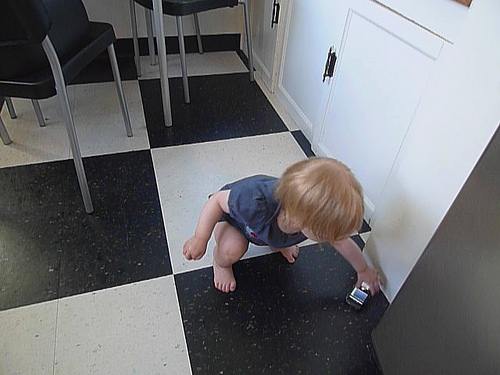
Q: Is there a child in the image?
A: Yes, there is a child.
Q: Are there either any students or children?
A: Yes, there is a child.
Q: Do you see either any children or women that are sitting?
A: Yes, the child is sitting.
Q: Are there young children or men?
A: Yes, there is a young child.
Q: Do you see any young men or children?
A: Yes, there is a young child.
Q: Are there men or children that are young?
A: Yes, the child is young.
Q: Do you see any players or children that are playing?
A: Yes, the child is playing.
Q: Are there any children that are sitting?
A: Yes, there is a child that is sitting.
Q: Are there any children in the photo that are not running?
A: Yes, there is a child that is sitting.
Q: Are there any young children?
A: Yes, there is a young child.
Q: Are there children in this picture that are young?
A: Yes, there is a child that is young.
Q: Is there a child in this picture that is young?
A: Yes, there is a child that is young.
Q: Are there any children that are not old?
A: Yes, there is an young child.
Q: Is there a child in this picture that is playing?
A: Yes, there is a child that is playing.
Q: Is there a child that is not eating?
A: Yes, there is a child that is playing.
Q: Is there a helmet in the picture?
A: No, there are no helmets.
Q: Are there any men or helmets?
A: No, there are no helmets or men.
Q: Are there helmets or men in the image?
A: No, there are no helmets or men.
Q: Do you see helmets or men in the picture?
A: No, there are no helmets or men.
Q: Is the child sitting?
A: Yes, the child is sitting.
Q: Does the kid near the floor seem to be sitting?
A: Yes, the kid is sitting.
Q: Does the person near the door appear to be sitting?
A: Yes, the kid is sitting.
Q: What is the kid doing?
A: The kid is sitting.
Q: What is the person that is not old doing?
A: The kid is sitting.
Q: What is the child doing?
A: The kid is sitting.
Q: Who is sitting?
A: The child is sitting.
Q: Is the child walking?
A: No, the child is sitting.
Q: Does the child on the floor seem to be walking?
A: No, the child is sitting.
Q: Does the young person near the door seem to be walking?
A: No, the child is sitting.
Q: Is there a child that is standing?
A: No, there is a child but he is sitting.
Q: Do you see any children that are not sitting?
A: No, there is a child but he is sitting.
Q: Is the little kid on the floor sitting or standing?
A: The kid is sitting.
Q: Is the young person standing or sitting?
A: The kid is sitting.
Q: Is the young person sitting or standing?
A: The kid is sitting.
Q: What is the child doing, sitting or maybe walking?
A: The child is sitting.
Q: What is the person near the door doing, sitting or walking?
A: The child is sitting.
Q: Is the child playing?
A: Yes, the child is playing.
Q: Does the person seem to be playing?
A: Yes, the kid is playing.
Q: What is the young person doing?
A: The child is playing.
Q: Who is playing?
A: The child is playing.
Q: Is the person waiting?
A: No, the kid is playing.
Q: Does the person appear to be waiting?
A: No, the kid is playing.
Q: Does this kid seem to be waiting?
A: No, the kid is playing.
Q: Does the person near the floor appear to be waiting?
A: No, the kid is playing.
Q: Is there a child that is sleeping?
A: No, there is a child but he is playing.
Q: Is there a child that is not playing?
A: No, there is a child but he is playing.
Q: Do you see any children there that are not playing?
A: No, there is a child but he is playing.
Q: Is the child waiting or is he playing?
A: The child is playing.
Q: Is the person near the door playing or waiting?
A: The child is playing.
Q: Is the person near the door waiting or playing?
A: The child is playing.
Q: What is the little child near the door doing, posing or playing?
A: The child is playing.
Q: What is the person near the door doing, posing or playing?
A: The child is playing.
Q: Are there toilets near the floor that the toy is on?
A: No, there is a child near the floor.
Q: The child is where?
A: The child is on the floor.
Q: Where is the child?
A: The child is on the floor.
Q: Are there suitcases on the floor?
A: No, there is a child on the floor.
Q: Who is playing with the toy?
A: The kid is playing with the toy.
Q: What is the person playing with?
A: The kid is playing with a toy.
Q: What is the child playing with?
A: The kid is playing with a toy.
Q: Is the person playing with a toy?
A: Yes, the kid is playing with a toy.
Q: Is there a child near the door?
A: Yes, there is a child near the door.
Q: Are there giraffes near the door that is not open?
A: No, there is a child near the door.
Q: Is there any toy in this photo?
A: Yes, there is a toy.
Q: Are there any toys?
A: Yes, there is a toy.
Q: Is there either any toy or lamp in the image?
A: Yes, there is a toy.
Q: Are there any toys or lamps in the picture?
A: Yes, there is a toy.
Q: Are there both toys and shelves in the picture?
A: No, there is a toy but no shelves.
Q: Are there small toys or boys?
A: Yes, there is a small toy.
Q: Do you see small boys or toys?
A: Yes, there is a small toy.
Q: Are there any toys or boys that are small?
A: Yes, the toy is small.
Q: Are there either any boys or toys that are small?
A: Yes, the toy is small.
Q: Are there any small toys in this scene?
A: Yes, there is a small toy.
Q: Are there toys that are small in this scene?
A: Yes, there is a small toy.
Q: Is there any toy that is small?
A: Yes, there is a toy that is small.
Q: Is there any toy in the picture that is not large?
A: Yes, there is a small toy.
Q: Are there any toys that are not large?
A: Yes, there is a small toy.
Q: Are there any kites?
A: No, there are no kites.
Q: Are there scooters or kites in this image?
A: No, there are no kites or scooters.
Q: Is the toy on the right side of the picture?
A: Yes, the toy is on the right of the image.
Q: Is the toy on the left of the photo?
A: No, the toy is on the right of the image.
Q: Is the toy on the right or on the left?
A: The toy is on the right of the image.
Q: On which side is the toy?
A: The toy is on the right of the image.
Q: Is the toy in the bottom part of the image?
A: Yes, the toy is in the bottom of the image.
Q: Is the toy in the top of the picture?
A: No, the toy is in the bottom of the image.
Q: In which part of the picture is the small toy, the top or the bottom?
A: The toy is in the bottom of the image.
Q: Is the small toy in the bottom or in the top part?
A: The toy is in the bottom of the image.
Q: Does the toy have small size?
A: Yes, the toy is small.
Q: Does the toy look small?
A: Yes, the toy is small.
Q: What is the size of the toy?
A: The toy is small.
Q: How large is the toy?
A: The toy is small.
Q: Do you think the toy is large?
A: No, the toy is small.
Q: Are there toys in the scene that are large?
A: No, there is a toy but it is small.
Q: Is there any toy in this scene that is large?
A: No, there is a toy but it is small.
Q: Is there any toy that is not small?
A: No, there is a toy but it is small.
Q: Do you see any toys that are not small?
A: No, there is a toy but it is small.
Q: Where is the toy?
A: The toy is on the floor.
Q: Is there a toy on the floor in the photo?
A: Yes, there is a toy on the floor.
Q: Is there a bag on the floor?
A: No, there is a toy on the floor.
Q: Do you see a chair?
A: Yes, there is a chair.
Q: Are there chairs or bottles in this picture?
A: Yes, there is a chair.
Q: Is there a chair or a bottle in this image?
A: Yes, there is a chair.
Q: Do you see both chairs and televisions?
A: No, there is a chair but no televisions.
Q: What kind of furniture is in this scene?
A: The furniture is a chair.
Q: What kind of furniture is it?
A: The piece of furniture is a chair.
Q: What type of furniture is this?
A: That is a chair.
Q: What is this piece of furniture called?
A: That is a chair.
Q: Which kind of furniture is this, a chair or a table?
A: That is a chair.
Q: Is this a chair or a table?
A: This is a chair.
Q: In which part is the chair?
A: The chair is on the left of the image.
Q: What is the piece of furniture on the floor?
A: The piece of furniture is a chair.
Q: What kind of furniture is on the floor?
A: The piece of furniture is a chair.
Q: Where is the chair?
A: The chair is on the floor.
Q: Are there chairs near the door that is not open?
A: Yes, there is a chair near the door.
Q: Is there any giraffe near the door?
A: No, there is a chair near the door.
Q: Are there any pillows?
A: No, there are no pillows.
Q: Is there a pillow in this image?
A: No, there are no pillows.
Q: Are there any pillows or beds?
A: No, there are no pillows or beds.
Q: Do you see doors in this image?
A: Yes, there is a door.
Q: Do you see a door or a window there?
A: Yes, there is a door.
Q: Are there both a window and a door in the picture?
A: No, there is a door but no windows.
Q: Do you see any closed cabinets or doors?
A: Yes, there is a closed door.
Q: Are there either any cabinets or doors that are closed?
A: Yes, the door is closed.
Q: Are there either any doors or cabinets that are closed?
A: Yes, the door is closed.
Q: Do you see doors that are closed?
A: Yes, there is a closed door.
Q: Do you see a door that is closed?
A: Yes, there is a door that is closed.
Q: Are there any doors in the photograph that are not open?
A: Yes, there is an closed door.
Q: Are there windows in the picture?
A: No, there are no windows.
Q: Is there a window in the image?
A: No, there are no windows.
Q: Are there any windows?
A: No, there are no windows.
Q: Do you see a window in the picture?
A: No, there are no windows.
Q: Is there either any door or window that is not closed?
A: No, there is a door but it is closed.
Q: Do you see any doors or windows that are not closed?
A: No, there is a door but it is closed.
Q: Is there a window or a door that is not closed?
A: No, there is a door but it is closed.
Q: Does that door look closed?
A: Yes, the door is closed.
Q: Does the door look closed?
A: Yes, the door is closed.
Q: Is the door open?
A: No, the door is closed.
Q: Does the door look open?
A: No, the door is closed.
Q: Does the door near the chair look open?
A: No, the door is closed.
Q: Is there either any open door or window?
A: No, there is a door but it is closed.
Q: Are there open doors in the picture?
A: No, there is a door but it is closed.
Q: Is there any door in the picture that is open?
A: No, there is a door but it is closed.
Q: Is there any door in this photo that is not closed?
A: No, there is a door but it is closed.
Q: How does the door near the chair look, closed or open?
A: The door is closed.